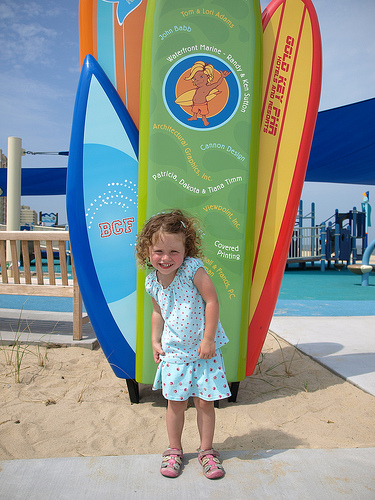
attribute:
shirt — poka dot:
[138, 257, 233, 362]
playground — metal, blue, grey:
[309, 197, 373, 282]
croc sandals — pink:
[148, 443, 233, 478]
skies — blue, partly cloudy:
[4, 30, 69, 134]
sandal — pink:
[145, 445, 267, 484]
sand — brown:
[1, 323, 373, 451]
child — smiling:
[141, 212, 227, 478]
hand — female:
[198, 336, 214, 358]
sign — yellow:
[249, 0, 322, 387]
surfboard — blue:
[62, 53, 138, 375]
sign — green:
[135, 0, 263, 383]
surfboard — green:
[132, 1, 263, 385]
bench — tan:
[2, 225, 111, 347]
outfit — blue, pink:
[161, 313, 205, 354]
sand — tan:
[9, 359, 145, 456]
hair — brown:
[131, 206, 205, 274]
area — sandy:
[5, 312, 315, 456]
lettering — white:
[156, 162, 246, 196]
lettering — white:
[212, 235, 239, 262]